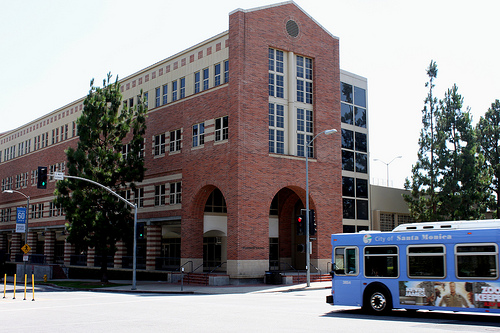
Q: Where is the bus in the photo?
A: The street.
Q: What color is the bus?
A: Blue.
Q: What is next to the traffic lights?
A: A building.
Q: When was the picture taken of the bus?
A: Daytime.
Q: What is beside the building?
A: A tree.